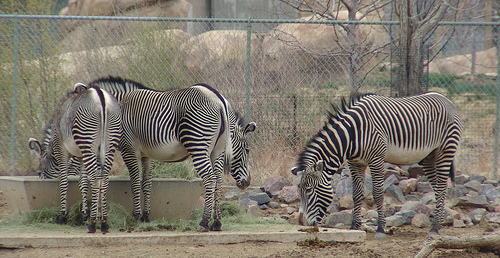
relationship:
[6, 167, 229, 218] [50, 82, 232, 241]
trough near zebras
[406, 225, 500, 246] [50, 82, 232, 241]
branch aside zebras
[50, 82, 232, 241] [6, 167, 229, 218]
zebras eating from trough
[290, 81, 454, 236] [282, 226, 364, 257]
zebra eating off ground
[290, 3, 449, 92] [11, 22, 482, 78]
tree behind fence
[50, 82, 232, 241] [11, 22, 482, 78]
zebras in front of fence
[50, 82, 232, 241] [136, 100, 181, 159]
zebras have stripes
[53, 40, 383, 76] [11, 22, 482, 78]
rocks behind fence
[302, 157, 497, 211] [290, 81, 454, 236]
rocks behind zebra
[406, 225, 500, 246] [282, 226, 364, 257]
branch on ground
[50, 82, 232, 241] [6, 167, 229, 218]
zebras at trough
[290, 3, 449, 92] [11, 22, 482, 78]
trees near fence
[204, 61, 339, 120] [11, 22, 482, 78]
hay behind fence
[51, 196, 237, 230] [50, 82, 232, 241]
hay near zebras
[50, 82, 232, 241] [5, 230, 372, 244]
zebras on concrete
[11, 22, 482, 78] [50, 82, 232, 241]
fence behind zebras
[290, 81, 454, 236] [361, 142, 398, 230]
zebra has leg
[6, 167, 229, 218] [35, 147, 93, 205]
trough for feeding